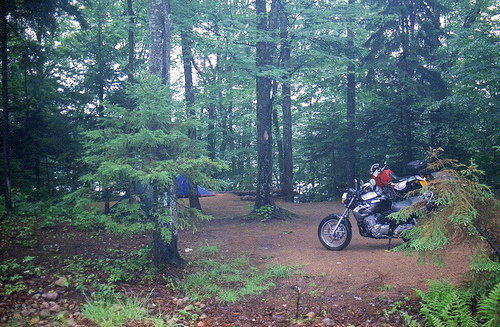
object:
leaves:
[134, 80, 171, 123]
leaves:
[253, 65, 293, 81]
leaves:
[155, 215, 176, 243]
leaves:
[362, 101, 393, 131]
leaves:
[190, 158, 231, 176]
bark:
[263, 128, 270, 139]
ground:
[388, 127, 413, 152]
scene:
[44, 19, 361, 307]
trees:
[2, 1, 54, 209]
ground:
[255, 245, 298, 297]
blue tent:
[163, 172, 227, 207]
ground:
[259, 223, 363, 287]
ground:
[180, 190, 472, 323]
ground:
[1, 191, 498, 323]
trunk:
[253, 4, 275, 208]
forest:
[75, 41, 330, 149]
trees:
[334, 1, 362, 188]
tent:
[110, 171, 215, 208]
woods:
[155, 191, 186, 264]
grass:
[69, 234, 320, 325]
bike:
[318, 154, 443, 249]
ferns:
[404, 262, 497, 319]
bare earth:
[176, 185, 472, 281]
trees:
[2, 0, 76, 280]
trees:
[87, 0, 151, 231]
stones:
[37, 291, 62, 315]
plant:
[383, 142, 498, 276]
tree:
[252, 4, 274, 209]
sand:
[0, 190, 498, 324]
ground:
[76, 230, 408, 296]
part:
[322, 220, 345, 247]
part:
[236, 287, 406, 327]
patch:
[184, 228, 424, 274]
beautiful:
[252, 128, 472, 267]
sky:
[92, 51, 438, 180]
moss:
[260, 171, 272, 194]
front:
[317, 215, 354, 249]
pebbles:
[194, 310, 212, 319]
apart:
[47, 200, 122, 275]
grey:
[157, 196, 174, 207]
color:
[381, 174, 391, 183]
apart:
[113, 253, 160, 278]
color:
[72, 201, 440, 327]